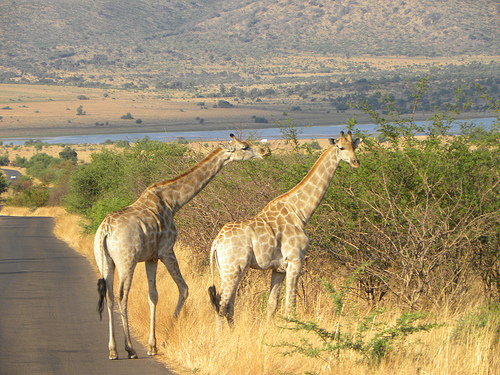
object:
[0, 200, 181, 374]
giraffes road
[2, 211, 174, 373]
road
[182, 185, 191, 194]
spot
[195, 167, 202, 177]
spot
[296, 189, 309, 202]
spot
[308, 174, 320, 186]
spot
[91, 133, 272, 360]
animal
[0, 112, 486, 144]
water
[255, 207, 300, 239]
spots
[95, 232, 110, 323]
tail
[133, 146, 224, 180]
mane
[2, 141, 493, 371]
bushes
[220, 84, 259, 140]
sky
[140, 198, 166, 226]
spots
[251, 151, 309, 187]
tree top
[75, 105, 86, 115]
bush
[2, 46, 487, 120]
dirt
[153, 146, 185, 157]
tree top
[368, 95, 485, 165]
tree top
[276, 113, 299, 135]
tree top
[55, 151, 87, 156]
tree top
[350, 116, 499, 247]
food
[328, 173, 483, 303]
stems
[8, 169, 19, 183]
vehicle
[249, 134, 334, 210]
mane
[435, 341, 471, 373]
grass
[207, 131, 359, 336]
animal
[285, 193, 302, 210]
spots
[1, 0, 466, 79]
distance